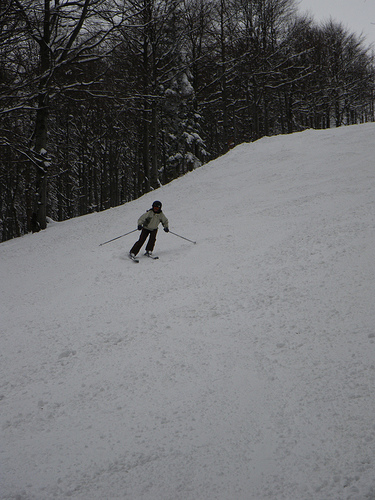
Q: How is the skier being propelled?
A: Gravity.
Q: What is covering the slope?
A: Snow.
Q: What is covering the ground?
A: Snow.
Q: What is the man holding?
A: Ski poles.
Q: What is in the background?
A: Trees.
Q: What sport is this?
A: Skiing.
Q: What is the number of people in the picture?
A: One.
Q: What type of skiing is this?
A: Downhill skiing.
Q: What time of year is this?
A: Winter.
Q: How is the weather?
A: Cold.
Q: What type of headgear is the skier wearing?
A: Helmet.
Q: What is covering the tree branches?
A: Snow.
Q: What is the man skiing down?
A: A hill.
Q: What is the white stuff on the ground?
A: Snow.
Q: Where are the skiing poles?
A: In the skier's hands.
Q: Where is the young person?
A: On a hill.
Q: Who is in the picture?
A: A young person.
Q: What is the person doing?
A: Skiing.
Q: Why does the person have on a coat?
A: It's cold.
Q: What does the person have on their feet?
A: Skis.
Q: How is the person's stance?
A: Leaning.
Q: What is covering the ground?
A: Snow.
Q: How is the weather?
A: Cloudy.